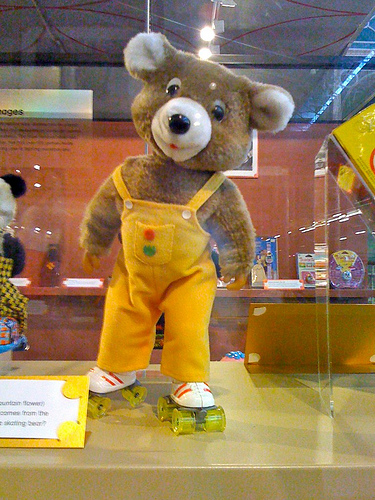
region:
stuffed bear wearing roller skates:
[45, 41, 270, 436]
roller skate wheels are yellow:
[92, 387, 248, 458]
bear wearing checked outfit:
[1, 262, 34, 336]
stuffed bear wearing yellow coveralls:
[98, 156, 266, 393]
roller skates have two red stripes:
[88, 350, 235, 443]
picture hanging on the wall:
[216, 116, 279, 192]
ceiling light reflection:
[184, 13, 253, 67]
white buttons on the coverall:
[126, 190, 199, 222]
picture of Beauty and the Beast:
[248, 232, 287, 293]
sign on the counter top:
[259, 265, 318, 296]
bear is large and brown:
[80, 31, 259, 447]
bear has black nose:
[163, 99, 194, 144]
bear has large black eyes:
[162, 86, 224, 121]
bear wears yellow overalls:
[109, 150, 215, 401]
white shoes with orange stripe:
[90, 342, 208, 411]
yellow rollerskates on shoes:
[140, 386, 227, 434]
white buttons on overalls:
[120, 197, 194, 246]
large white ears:
[126, 32, 171, 89]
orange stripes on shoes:
[164, 377, 218, 413]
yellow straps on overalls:
[104, 156, 147, 216]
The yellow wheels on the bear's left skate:
[155, 391, 224, 432]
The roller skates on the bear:
[82, 365, 228, 440]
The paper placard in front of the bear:
[0, 368, 92, 449]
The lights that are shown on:
[188, 15, 239, 65]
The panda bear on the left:
[0, 166, 37, 347]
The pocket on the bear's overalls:
[128, 219, 181, 268]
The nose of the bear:
[165, 112, 190, 136]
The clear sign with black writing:
[0, 83, 100, 175]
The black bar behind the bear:
[0, 44, 373, 78]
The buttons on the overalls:
[120, 197, 193, 221]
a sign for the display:
[0, 374, 95, 453]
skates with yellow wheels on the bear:
[76, 370, 236, 445]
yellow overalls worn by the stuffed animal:
[92, 162, 231, 375]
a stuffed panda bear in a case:
[0, 170, 33, 277]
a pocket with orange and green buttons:
[128, 216, 183, 277]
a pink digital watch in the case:
[248, 236, 282, 287]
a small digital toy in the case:
[294, 247, 326, 290]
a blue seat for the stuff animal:
[0, 324, 33, 377]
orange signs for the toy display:
[5, 268, 318, 295]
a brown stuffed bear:
[66, 27, 304, 435]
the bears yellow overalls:
[95, 161, 221, 380]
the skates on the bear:
[85, 360, 225, 432]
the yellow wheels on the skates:
[88, 385, 224, 432]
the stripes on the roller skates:
[173, 381, 190, 398]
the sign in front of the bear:
[1, 373, 87, 450]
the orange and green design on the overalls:
[140, 229, 156, 255]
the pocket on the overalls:
[133, 219, 173, 265]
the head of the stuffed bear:
[124, 32, 297, 169]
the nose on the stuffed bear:
[170, 114, 190, 132]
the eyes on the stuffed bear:
[166, 75, 227, 120]